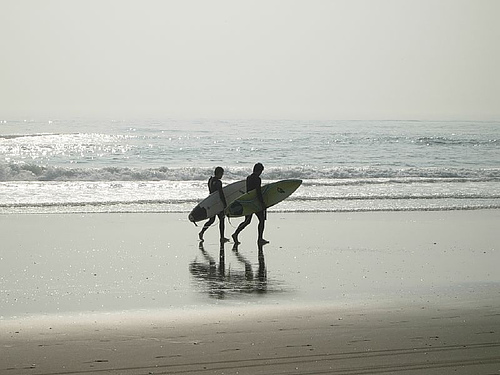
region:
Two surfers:
[146, 153, 456, 355]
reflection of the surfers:
[168, 215, 348, 342]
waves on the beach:
[101, 139, 173, 217]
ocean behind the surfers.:
[123, 143, 204, 165]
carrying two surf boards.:
[182, 168, 467, 292]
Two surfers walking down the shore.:
[161, 153, 358, 346]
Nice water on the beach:
[121, 138, 306, 255]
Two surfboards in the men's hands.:
[171, 151, 399, 266]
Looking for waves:
[176, 159, 336, 319]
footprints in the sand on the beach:
[91, 227, 363, 367]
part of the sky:
[336, 53, 397, 95]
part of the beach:
[303, 308, 353, 360]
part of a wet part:
[298, 262, 349, 303]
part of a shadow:
[234, 263, 266, 309]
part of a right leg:
[251, 220, 269, 240]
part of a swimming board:
[220, 202, 264, 221]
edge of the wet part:
[181, 290, 245, 336]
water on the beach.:
[40, 242, 130, 282]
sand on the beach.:
[303, 338, 443, 343]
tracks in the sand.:
[340, 346, 487, 363]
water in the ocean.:
[87, 127, 373, 148]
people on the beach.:
[191, 157, 300, 243]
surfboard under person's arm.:
[243, 177, 291, 216]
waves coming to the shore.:
[316, 160, 469, 183]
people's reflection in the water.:
[191, 263, 283, 295]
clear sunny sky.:
[99, 25, 389, 57]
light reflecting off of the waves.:
[25, 132, 118, 159]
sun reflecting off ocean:
[26, 133, 96, 164]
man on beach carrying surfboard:
[227, 155, 300, 255]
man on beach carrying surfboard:
[181, 160, 236, 241]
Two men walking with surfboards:
[181, 156, 303, 246]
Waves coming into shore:
[348, 158, 450, 218]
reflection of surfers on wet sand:
[184, 238, 285, 305]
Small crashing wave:
[33, 154, 126, 218]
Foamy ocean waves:
[13, 176, 90, 213]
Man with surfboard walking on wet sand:
[223, 153, 303, 247]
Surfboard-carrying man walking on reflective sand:
[187, 153, 233, 248]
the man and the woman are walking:
[197, 161, 275, 254]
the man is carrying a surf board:
[242, 173, 307, 221]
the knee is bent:
[235, 216, 256, 237]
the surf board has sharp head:
[283, 174, 305, 191]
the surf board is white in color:
[268, 173, 302, 204]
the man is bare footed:
[228, 231, 278, 250]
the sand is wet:
[191, 264, 301, 303]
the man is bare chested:
[247, 180, 259, 188]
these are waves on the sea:
[2, 126, 110, 193]